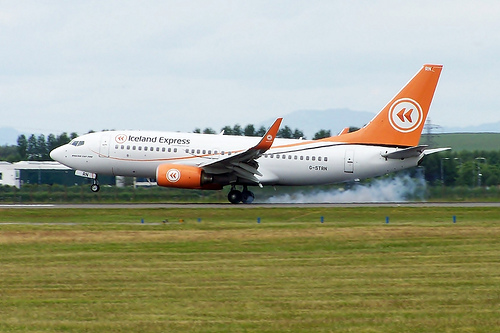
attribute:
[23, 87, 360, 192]
plane — white, orange, under, landing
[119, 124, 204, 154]
lettering — iceland express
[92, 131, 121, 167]
door — white, back, entrance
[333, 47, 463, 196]
tail — fin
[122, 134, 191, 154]
logo — iceland, circular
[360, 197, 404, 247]
marker — blue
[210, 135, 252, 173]
wing — white, turned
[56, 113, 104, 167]
cabin — pilot